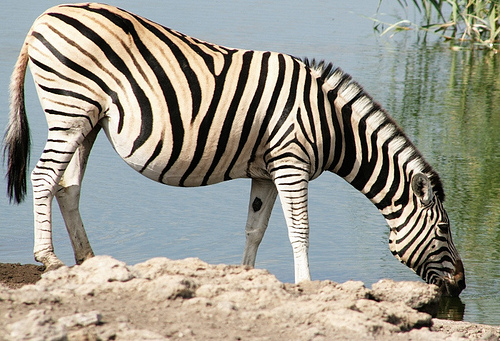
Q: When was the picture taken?
A: Daytime.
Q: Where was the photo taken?
A: Near the water.